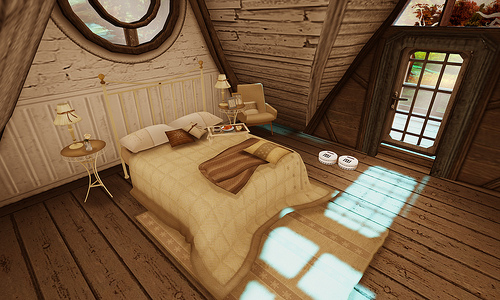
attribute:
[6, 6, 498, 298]
photograph — cartoon 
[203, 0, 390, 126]
wall — wood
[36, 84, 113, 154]
lampshade — brown, ivory 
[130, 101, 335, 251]
bed — brown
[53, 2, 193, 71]
window — round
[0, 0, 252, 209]
wall — brown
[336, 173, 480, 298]
floor — brown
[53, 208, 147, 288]
floor — brown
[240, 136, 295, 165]
pillow — small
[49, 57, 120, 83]
bedroom wall — white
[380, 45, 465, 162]
door — brown, wooden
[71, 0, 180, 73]
window — round 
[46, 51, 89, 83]
wall — brick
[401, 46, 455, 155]
panes — glass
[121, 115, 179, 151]
pillow — white